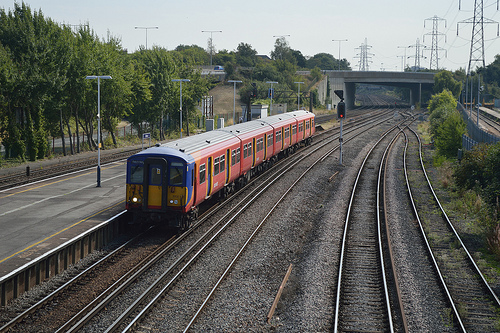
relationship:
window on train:
[230, 150, 240, 163] [126, 108, 316, 228]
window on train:
[254, 131, 270, 163] [126, 108, 316, 228]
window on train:
[196, 159, 207, 187] [114, 102, 318, 239]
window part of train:
[213, 158, 219, 173] [126, 108, 316, 228]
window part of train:
[217, 152, 230, 171] [114, 102, 318, 239]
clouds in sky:
[314, 9, 419, 61] [4, 1, 484, 87]